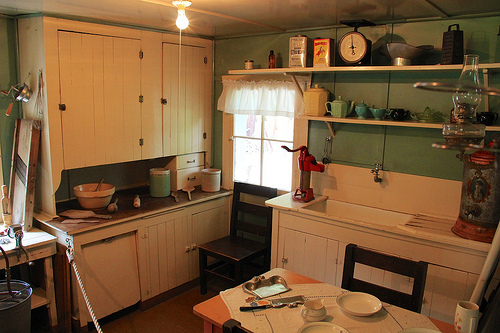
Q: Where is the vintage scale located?
A: On the top shelf.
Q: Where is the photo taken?
A: Kitchen.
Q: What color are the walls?
A: Green.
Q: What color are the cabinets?
A: White.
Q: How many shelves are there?
A: Two.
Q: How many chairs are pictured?
A: Two.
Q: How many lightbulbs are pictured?
A: One.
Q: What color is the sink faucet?
A: Red.